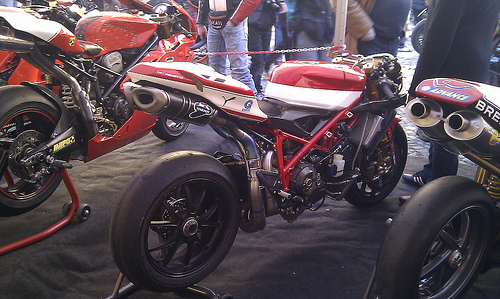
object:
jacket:
[329, 1, 374, 51]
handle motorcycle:
[364, 80, 399, 107]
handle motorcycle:
[176, 15, 203, 60]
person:
[399, 0, 498, 188]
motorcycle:
[1, 6, 200, 215]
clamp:
[1, 132, 93, 253]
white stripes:
[411, 176, 427, 187]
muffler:
[405, 98, 484, 148]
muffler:
[122, 85, 172, 107]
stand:
[50, 158, 98, 226]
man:
[194, 0, 260, 96]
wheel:
[105, 145, 245, 297]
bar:
[8, 177, 73, 262]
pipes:
[441, 107, 499, 161]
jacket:
[413, 2, 498, 92]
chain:
[196, 42, 331, 57]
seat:
[252, 95, 287, 117]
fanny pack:
[203, 15, 228, 33]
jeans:
[205, 16, 257, 96]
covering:
[0, 154, 500, 296]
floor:
[0, 24, 498, 296]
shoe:
[398, 167, 432, 188]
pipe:
[131, 84, 218, 127]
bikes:
[110, 49, 412, 294]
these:
[412, 97, 452, 162]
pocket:
[213, 50, 243, 90]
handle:
[38, 50, 98, 112]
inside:
[2, 49, 481, 281]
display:
[97, 51, 413, 299]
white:
[264, 79, 366, 113]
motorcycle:
[370, 62, 498, 294]